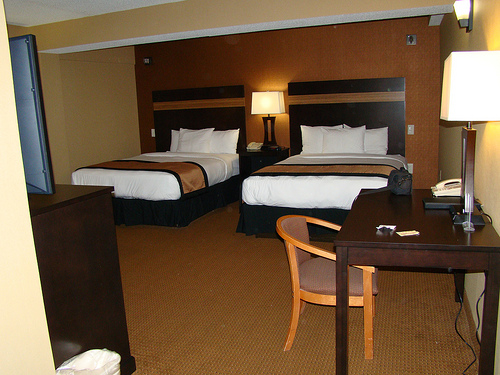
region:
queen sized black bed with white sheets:
[236, 76, 406, 239]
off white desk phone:
[431, 177, 463, 197]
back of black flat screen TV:
[6, 33, 56, 195]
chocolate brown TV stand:
[26, 182, 138, 373]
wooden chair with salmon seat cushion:
[275, 213, 377, 358]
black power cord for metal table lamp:
[441, 51, 499, 373]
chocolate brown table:
[333, 187, 498, 373]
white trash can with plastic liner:
[55, 347, 122, 374]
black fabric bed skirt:
[236, 202, 349, 237]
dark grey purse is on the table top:
[335, 166, 499, 250]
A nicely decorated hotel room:
[21, 20, 481, 322]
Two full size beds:
[56, 51, 413, 226]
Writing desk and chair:
[287, 152, 476, 356]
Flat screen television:
[7, 35, 142, 293]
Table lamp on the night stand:
[233, 55, 306, 223]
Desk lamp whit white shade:
[403, 47, 498, 171]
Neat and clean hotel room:
[46, 59, 424, 352]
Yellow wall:
[43, 18, 157, 159]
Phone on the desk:
[420, 150, 481, 218]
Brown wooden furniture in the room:
[32, 145, 478, 297]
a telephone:
[422, 170, 472, 215]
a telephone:
[421, 160, 468, 194]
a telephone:
[430, 152, 491, 233]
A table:
[334, 171, 431, 361]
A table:
[345, 243, 376, 336]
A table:
[339, 131, 413, 311]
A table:
[316, 182, 379, 276]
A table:
[330, 94, 462, 276]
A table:
[305, 211, 405, 373]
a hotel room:
[15, 3, 493, 364]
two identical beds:
[93, 72, 406, 227]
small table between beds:
[194, 141, 313, 216]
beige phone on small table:
[238, 135, 266, 157]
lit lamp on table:
[238, 84, 289, 166]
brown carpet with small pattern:
[155, 259, 227, 334]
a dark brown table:
[335, 177, 496, 372]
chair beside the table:
[270, 205, 406, 372]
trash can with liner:
[52, 340, 128, 371]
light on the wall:
[446, 0, 484, 40]